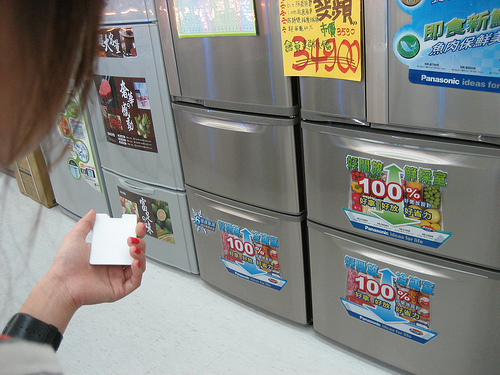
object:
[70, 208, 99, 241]
fingers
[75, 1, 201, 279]
refridgerator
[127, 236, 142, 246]
painted red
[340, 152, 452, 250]
sign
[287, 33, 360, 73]
lettering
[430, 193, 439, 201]
grapes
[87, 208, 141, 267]
phone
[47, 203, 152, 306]
hand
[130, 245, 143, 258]
nail polish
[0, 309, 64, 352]
wrist band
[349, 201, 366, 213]
tomatoes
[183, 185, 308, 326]
drawer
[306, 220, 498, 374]
drawer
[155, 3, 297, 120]
drawer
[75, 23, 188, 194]
door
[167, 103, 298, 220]
drawer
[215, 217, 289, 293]
sticker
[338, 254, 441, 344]
sticker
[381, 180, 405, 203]
number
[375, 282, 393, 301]
number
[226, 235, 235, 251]
number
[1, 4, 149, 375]
girl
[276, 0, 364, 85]
display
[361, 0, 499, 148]
box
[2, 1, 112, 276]
hair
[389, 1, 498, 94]
sticker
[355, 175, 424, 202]
100%